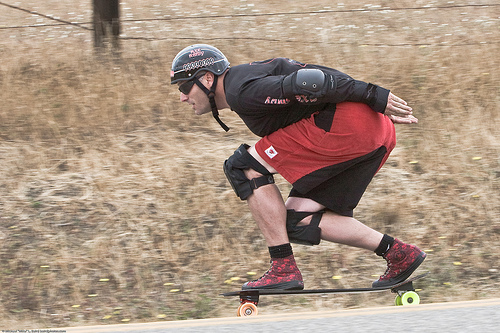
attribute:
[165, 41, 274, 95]
helmet — worn, red, black, protective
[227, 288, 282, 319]
skateboard — yellow, peach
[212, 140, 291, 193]
kneepads — worn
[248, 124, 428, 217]
shorts — black, red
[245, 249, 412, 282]
sneakers — red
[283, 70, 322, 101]
pads — black, worn, protective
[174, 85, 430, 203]
man — crouched, wearing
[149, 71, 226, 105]
sunglasses — worn, black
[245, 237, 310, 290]
shoes — red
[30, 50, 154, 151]
grass — dead